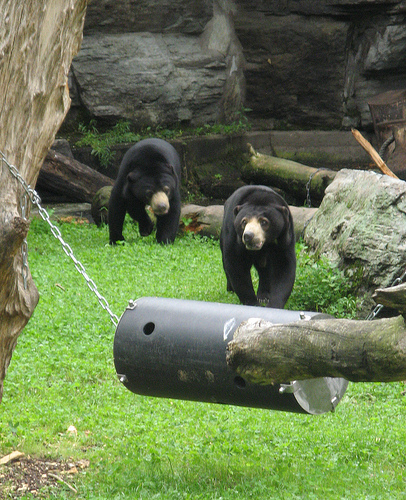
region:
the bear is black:
[103, 128, 180, 233]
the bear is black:
[221, 180, 327, 322]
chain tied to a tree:
[12, 158, 115, 332]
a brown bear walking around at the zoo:
[214, 182, 295, 306]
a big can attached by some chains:
[114, 291, 344, 418]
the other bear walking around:
[106, 133, 184, 250]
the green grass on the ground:
[35, 221, 405, 497]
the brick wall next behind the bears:
[84, 4, 404, 125]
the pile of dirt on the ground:
[0, 459, 62, 494]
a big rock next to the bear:
[296, 169, 405, 275]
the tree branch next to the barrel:
[219, 314, 404, 389]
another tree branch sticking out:
[347, 127, 397, 175]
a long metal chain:
[0, 160, 119, 342]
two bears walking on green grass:
[98, 134, 301, 312]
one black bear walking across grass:
[206, 175, 304, 308]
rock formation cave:
[85, 3, 405, 128]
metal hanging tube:
[1, 148, 387, 425]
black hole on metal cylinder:
[137, 313, 161, 344]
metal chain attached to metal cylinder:
[0, 154, 117, 334]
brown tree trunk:
[3, 1, 90, 400]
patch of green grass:
[96, 411, 215, 495]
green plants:
[78, 109, 257, 143]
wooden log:
[250, 143, 331, 198]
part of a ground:
[168, 438, 194, 473]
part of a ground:
[198, 460, 222, 494]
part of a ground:
[176, 414, 202, 452]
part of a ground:
[25, 460, 49, 493]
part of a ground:
[198, 430, 232, 472]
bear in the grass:
[186, 163, 338, 333]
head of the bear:
[225, 204, 280, 250]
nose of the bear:
[236, 224, 260, 244]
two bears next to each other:
[69, 74, 351, 310]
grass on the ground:
[145, 261, 196, 289]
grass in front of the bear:
[224, 429, 315, 479]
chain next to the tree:
[35, 202, 120, 318]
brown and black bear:
[198, 168, 319, 297]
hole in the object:
[127, 310, 182, 350]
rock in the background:
[120, 38, 227, 100]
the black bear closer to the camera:
[218, 184, 296, 308]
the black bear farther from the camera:
[105, 137, 181, 246]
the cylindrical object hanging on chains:
[113, 295, 349, 414]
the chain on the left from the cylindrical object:
[0, 150, 118, 323]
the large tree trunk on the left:
[0, 0, 89, 403]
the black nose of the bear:
[242, 231, 255, 242]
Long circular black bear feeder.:
[111, 293, 350, 415]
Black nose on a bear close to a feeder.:
[242, 231, 255, 243]